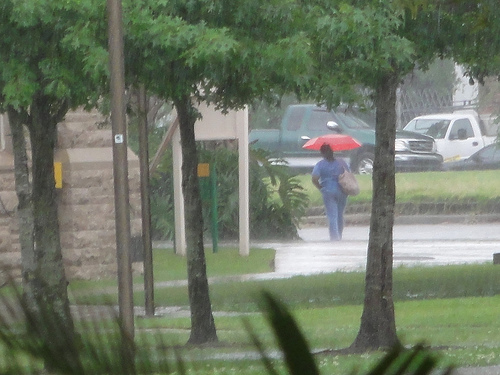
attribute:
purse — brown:
[341, 166, 356, 196]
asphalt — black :
[298, 222, 497, 242]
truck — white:
[405, 111, 499, 161]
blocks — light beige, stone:
[71, 164, 141, 190]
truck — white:
[398, 105, 495, 170]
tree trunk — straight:
[314, 82, 399, 362]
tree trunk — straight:
[33, 96, 74, 331]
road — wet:
[274, 221, 498, 279]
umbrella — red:
[302, 130, 364, 158]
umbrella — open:
[301, 130, 362, 187]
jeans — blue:
[313, 178, 354, 240]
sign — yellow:
[193, 162, 213, 179]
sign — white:
[167, 94, 244, 139]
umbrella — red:
[300, 133, 361, 151]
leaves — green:
[9, 6, 489, 100]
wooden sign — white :
[169, 69, 254, 259]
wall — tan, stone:
[58, 162, 113, 269]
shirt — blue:
[306, 154, 354, 196]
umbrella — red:
[303, 132, 383, 154]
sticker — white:
[112, 132, 124, 145]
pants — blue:
[320, 189, 349, 235]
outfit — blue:
[316, 158, 350, 235]